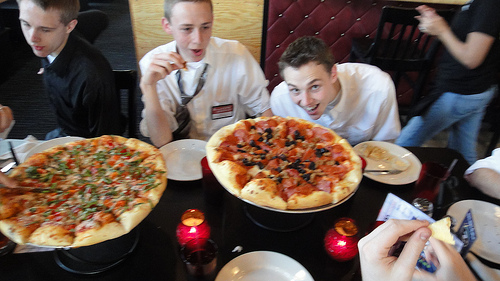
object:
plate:
[347, 138, 420, 187]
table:
[1, 137, 496, 281]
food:
[429, 216, 457, 246]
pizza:
[2, 133, 170, 250]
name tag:
[208, 102, 235, 120]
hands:
[351, 216, 479, 279]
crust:
[424, 217, 455, 246]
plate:
[444, 195, 497, 259]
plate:
[217, 250, 317, 281]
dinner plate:
[152, 139, 209, 180]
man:
[268, 37, 399, 143]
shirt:
[16, 35, 125, 138]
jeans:
[394, 89, 490, 166]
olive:
[242, 119, 339, 184]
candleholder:
[176, 237, 206, 246]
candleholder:
[329, 243, 355, 259]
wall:
[0, 0, 499, 138]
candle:
[174, 207, 213, 252]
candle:
[322, 215, 361, 260]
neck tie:
[170, 60, 210, 141]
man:
[132, 0, 278, 151]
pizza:
[201, 112, 361, 207]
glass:
[416, 156, 455, 197]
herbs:
[30, 155, 144, 233]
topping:
[251, 129, 265, 131]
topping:
[292, 158, 311, 168]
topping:
[279, 180, 307, 192]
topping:
[230, 129, 247, 139]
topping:
[263, 166, 285, 174]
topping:
[303, 190, 313, 191]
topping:
[325, 151, 341, 165]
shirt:
[126, 36, 276, 139]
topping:
[327, 192, 341, 197]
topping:
[234, 124, 240, 127]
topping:
[288, 128, 305, 139]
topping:
[236, 151, 244, 155]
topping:
[248, 181, 260, 182]